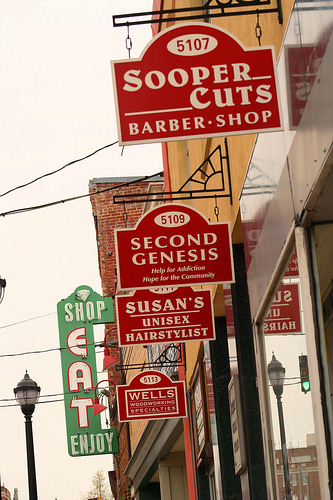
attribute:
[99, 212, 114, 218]
brick — brown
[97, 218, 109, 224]
brick — brown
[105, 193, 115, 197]
brick — brown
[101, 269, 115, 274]
brick — brown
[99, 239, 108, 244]
brick — brown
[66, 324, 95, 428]
letters — white, outlined in red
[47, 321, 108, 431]
word — eat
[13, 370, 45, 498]
lamp — street lamp, black , white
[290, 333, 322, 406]
traffic light — lit up green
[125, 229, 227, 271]
letters — white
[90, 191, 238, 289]
sign — red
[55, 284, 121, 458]
sign — green, white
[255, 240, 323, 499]
window — traffic light 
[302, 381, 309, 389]
light — green 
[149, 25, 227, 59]
number — 5109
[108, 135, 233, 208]
hanger — black, metal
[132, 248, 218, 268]
word — genesis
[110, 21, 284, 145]
sign — red, white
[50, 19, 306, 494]
sign — white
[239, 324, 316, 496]
lamp — street lamp